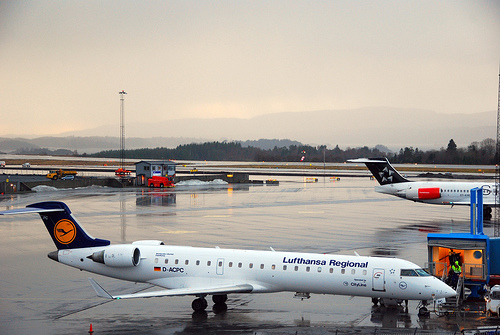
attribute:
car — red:
[140, 173, 172, 192]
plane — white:
[40, 200, 452, 317]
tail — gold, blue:
[25, 200, 110, 247]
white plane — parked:
[0, 200, 460, 317]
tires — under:
[180, 292, 230, 308]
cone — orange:
[143, 150, 478, 306]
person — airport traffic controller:
[441, 255, 464, 291]